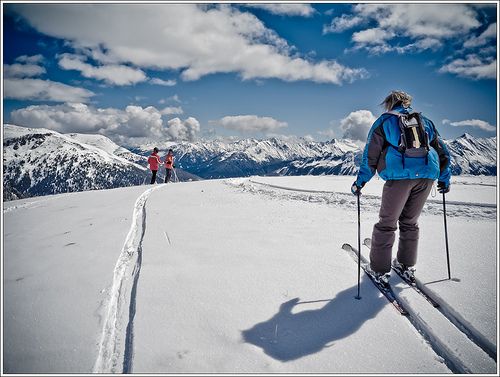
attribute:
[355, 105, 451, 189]
ski jacket — black, blue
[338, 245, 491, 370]
tracks — thin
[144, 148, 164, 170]
jacket — pink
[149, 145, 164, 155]
hat — black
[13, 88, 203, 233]
mountain — pointed, top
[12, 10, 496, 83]
white clouds — puffy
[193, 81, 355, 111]
sky — blue, clear, part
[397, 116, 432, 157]
backpack — gray, black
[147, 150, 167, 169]
jacket — red, white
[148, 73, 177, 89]
cloud — small, thin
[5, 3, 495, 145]
sky — blue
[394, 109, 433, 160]
backpack — gray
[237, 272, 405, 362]
shadow — skier's, dark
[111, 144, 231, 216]
hill — top